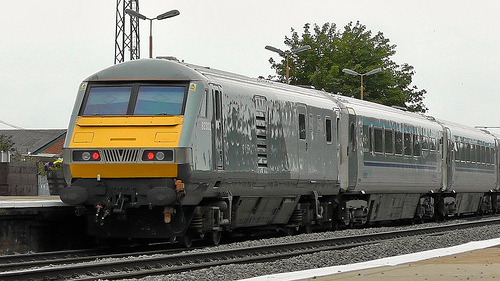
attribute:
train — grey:
[188, 106, 313, 250]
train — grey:
[286, 70, 333, 190]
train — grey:
[188, 82, 418, 212]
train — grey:
[349, 27, 393, 265]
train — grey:
[270, 95, 380, 176]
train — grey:
[273, 96, 416, 232]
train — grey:
[254, 62, 416, 220]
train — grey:
[324, 153, 379, 213]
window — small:
[109, 65, 195, 127]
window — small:
[113, 52, 225, 157]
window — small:
[138, 71, 162, 91]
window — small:
[41, 62, 203, 101]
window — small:
[363, 144, 400, 183]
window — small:
[379, 129, 436, 188]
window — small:
[370, 129, 428, 159]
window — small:
[400, 136, 422, 144]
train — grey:
[90, 71, 394, 203]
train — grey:
[104, 55, 354, 182]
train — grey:
[159, 55, 267, 199]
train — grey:
[300, 51, 451, 171]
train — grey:
[153, 141, 334, 221]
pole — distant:
[91, 9, 184, 62]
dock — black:
[37, 200, 75, 224]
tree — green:
[359, 51, 369, 76]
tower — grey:
[112, 27, 199, 90]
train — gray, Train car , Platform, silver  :
[59, 55, 497, 247]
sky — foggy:
[67, 3, 412, 49]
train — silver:
[58, 35, 461, 261]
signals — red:
[88, 133, 173, 168]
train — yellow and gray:
[39, 41, 368, 231]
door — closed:
[273, 95, 341, 195]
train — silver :
[53, 47, 472, 246]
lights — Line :
[79, 148, 166, 165]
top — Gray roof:
[154, 44, 386, 112]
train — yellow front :
[48, 45, 482, 225]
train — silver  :
[48, 56, 484, 233]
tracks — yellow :
[102, 242, 294, 278]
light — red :
[88, 145, 164, 161]